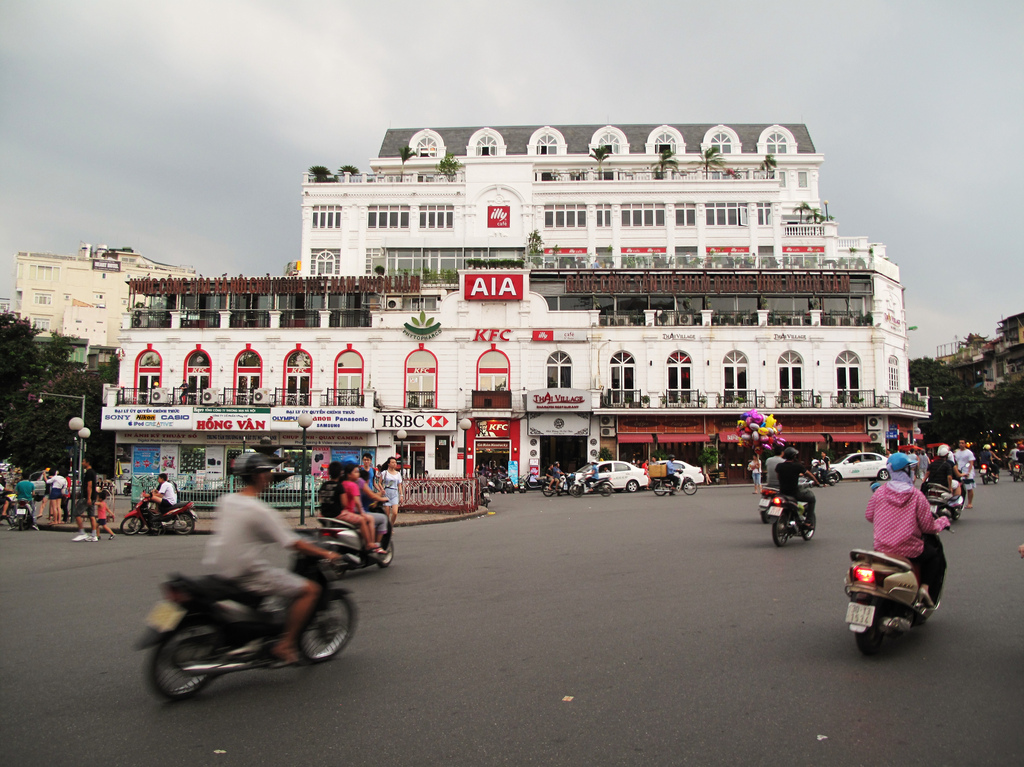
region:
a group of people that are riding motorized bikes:
[136, 432, 961, 692]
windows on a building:
[535, 195, 589, 234]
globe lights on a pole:
[58, 414, 91, 487]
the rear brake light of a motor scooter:
[827, 556, 903, 605]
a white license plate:
[845, 598, 877, 636]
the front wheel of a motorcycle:
[298, 582, 366, 666]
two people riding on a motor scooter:
[308, 449, 395, 573]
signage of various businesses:
[106, 404, 460, 431]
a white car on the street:
[816, 445, 894, 491]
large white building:
[93, 85, 966, 485]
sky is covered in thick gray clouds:
[2, 3, 1023, 380]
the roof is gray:
[380, 118, 811, 153]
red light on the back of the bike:
[854, 556, 878, 583]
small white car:
[577, 456, 651, 491]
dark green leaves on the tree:
[4, 307, 129, 485]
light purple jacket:
[849, 463, 970, 559]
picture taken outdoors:
[14, 14, 1020, 760]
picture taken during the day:
[23, 27, 1019, 765]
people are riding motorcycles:
[112, 406, 954, 713]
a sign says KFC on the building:
[472, 325, 505, 346]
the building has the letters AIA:
[462, 268, 526, 304]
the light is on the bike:
[858, 567, 877, 587]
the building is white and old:
[308, 113, 840, 390]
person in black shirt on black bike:
[768, 445, 819, 545]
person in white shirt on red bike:
[121, 470, 197, 532]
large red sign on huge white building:
[462, 273, 521, 299]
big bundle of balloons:
[732, 407, 784, 447]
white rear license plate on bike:
[845, 598, 872, 622]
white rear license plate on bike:
[765, 501, 784, 517]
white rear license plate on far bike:
[757, 494, 770, 507]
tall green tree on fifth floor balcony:
[792, 200, 809, 221]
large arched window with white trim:
[463, 125, 506, 158]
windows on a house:
[366, 200, 415, 240]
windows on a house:
[135, 355, 165, 403]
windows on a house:
[186, 361, 209, 396]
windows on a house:
[235, 365, 264, 401]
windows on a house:
[546, 348, 584, 407]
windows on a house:
[410, 206, 453, 220]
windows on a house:
[543, 197, 585, 226]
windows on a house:
[622, 200, 664, 227]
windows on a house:
[691, 200, 692, 223]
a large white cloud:
[155, 0, 386, 164]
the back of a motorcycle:
[849, 521, 941, 655]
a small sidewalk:
[399, 502, 450, 525]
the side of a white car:
[571, 456, 644, 492]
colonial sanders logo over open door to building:
[470, 417, 524, 441]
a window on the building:
[838, 353, 859, 393]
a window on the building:
[716, 344, 742, 427]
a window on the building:
[612, 354, 645, 427]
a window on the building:
[484, 344, 514, 427]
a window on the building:
[414, 340, 447, 445]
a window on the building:
[344, 363, 383, 437]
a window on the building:
[259, 326, 316, 440]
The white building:
[98, 123, 920, 474]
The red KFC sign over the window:
[471, 324, 517, 347]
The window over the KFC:
[465, 349, 516, 406]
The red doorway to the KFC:
[463, 416, 524, 486]